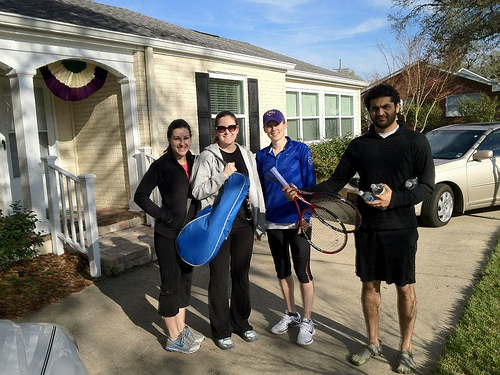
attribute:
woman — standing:
[195, 108, 284, 355]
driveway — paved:
[408, 242, 472, 308]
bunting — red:
[54, 57, 123, 112]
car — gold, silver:
[408, 114, 496, 211]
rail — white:
[36, 127, 101, 287]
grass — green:
[460, 239, 498, 372]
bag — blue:
[176, 177, 256, 266]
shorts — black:
[338, 200, 421, 301]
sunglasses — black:
[220, 130, 248, 148]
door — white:
[3, 90, 64, 204]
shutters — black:
[199, 69, 276, 174]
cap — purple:
[248, 111, 284, 127]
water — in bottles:
[348, 165, 384, 206]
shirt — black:
[318, 130, 432, 229]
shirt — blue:
[236, 150, 316, 236]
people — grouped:
[145, 96, 447, 375]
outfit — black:
[338, 128, 431, 280]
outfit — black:
[151, 141, 197, 317]